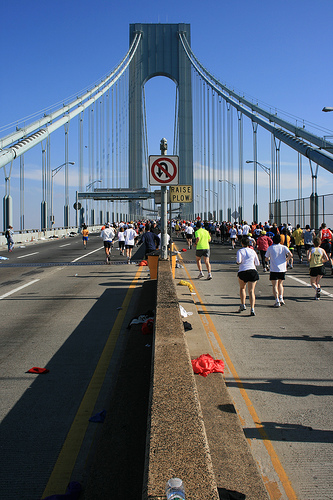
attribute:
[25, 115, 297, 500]
bridge — verazzano, running, beautiful, cement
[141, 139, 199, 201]
sign — no u-turn, raise, overhead, traffic, white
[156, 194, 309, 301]
people — running, three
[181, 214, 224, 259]
shirt — green, white, tee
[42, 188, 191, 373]
route — running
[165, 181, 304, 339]
group — large, runner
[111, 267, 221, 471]
barrier — cement, traffic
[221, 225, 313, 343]
women — running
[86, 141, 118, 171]
cloud — white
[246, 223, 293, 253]
jacket — orange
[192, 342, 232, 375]
plastic — large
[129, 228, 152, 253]
lid — black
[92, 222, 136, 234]
hats — white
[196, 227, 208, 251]
shirt — yellow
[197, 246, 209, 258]
shorts — black